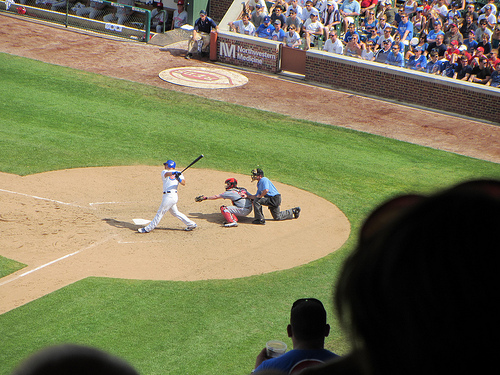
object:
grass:
[0, 52, 500, 375]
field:
[0, 0, 500, 375]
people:
[137, 159, 301, 233]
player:
[138, 159, 198, 234]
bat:
[176, 154, 204, 177]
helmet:
[163, 159, 176, 169]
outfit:
[144, 169, 196, 232]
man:
[247, 168, 301, 225]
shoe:
[185, 53, 193, 59]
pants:
[253, 194, 293, 221]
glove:
[176, 176, 182, 182]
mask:
[225, 182, 232, 188]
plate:
[132, 218, 151, 225]